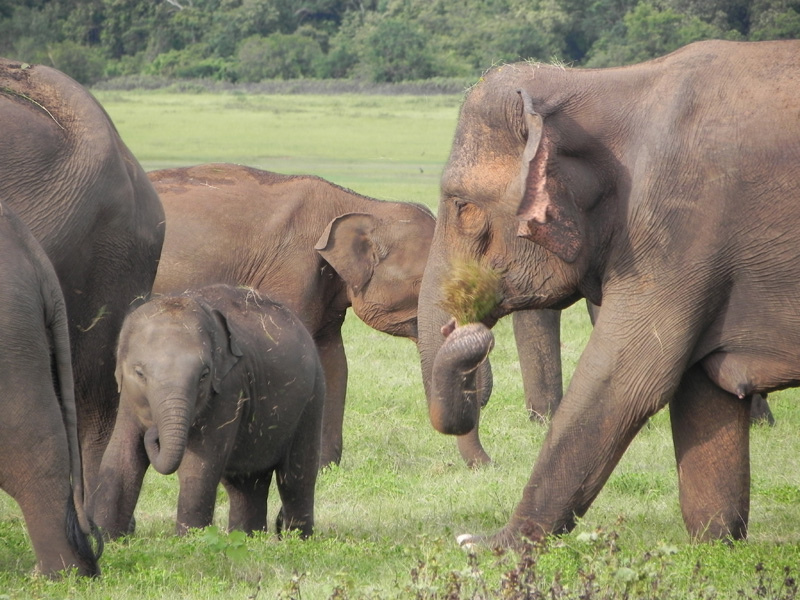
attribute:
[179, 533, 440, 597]
patch — grassy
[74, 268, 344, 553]
elephant — baby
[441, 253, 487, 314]
grass — clump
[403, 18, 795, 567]
elephant skin — gray, wrinkled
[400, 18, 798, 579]
elephant — adult, large, grey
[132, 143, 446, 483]
elephant — large, grey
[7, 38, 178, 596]
elephant — large, grey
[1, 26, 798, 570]
elephants — adult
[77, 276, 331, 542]
elephant — baby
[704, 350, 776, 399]
breast — milk-swollen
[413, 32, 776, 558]
elephant — adult, facing left, large, gray, brown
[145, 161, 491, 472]
elephant — adult, facing right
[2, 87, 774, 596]
grass — green, tall, yellow